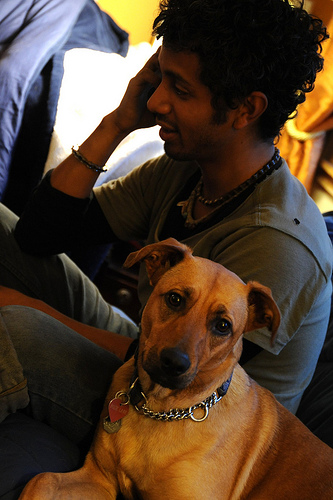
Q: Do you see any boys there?
A: No, there are no boys.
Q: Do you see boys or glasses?
A: No, there are no boys or glasses.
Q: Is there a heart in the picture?
A: Yes, there is a heart.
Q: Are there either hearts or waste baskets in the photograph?
A: Yes, there is a heart.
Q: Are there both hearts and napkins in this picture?
A: No, there is a heart but no napkins.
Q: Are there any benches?
A: No, there are no benches.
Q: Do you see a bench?
A: No, there are no benches.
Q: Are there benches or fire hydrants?
A: No, there are no benches or fire hydrants.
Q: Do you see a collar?
A: Yes, there is a collar.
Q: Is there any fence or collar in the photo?
A: Yes, there is a collar.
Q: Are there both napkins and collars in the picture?
A: No, there is a collar but no napkins.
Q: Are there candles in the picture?
A: No, there are no candles.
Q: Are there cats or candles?
A: No, there are no candles or cats.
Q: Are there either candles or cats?
A: No, there are no candles or cats.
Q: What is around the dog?
A: The collar is around the dog.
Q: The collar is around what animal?
A: The collar is around the dog.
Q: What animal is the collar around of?
A: The collar is around the dog.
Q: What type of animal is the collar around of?
A: The collar is around the dog.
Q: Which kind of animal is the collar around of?
A: The collar is around the dog.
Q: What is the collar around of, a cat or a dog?
A: The collar is around a dog.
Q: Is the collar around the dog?
A: Yes, the collar is around the dog.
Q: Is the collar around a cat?
A: No, the collar is around the dog.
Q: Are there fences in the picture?
A: No, there are no fences.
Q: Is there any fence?
A: No, there are no fences.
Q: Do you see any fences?
A: No, there are no fences.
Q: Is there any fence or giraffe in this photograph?
A: No, there are no fences or giraffes.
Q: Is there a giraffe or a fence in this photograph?
A: No, there are no fences or giraffes.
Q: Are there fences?
A: No, there are no fences.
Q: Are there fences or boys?
A: No, there are no fences or boys.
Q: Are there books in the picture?
A: No, there are no books.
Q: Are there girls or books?
A: No, there are no books or girls.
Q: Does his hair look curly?
A: Yes, the hair is curly.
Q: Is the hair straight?
A: No, the hair is curly.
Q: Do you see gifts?
A: No, there are no gifts.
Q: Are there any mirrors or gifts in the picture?
A: No, there are no gifts or mirrors.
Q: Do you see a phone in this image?
A: Yes, there is a phone.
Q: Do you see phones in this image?
A: Yes, there is a phone.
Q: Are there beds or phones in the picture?
A: Yes, there is a phone.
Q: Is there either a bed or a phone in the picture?
A: Yes, there is a phone.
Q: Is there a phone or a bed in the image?
A: Yes, there is a phone.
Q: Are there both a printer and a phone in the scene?
A: No, there is a phone but no printers.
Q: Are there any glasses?
A: No, there are no glasses.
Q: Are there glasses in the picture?
A: No, there are no glasses.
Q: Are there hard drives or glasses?
A: No, there are no glasses or hard drives.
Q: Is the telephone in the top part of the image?
A: Yes, the telephone is in the top of the image.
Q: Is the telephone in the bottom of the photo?
A: No, the telephone is in the top of the image.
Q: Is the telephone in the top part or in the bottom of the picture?
A: The telephone is in the top of the image.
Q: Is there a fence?
A: No, there are no fences.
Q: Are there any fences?
A: No, there are no fences.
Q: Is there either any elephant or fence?
A: No, there are no fences or elephants.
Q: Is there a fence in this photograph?
A: No, there are no fences.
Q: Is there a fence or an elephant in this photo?
A: No, there are no fences or elephants.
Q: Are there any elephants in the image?
A: No, there are no elephants.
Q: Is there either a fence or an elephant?
A: No, there are no elephants or fences.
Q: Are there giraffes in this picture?
A: No, there are no giraffes.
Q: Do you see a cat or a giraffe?
A: No, there are no giraffes or cats.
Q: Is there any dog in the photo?
A: Yes, there is a dog.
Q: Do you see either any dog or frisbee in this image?
A: Yes, there is a dog.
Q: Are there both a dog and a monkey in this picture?
A: No, there is a dog but no monkeys.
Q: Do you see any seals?
A: No, there are no seals.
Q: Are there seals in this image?
A: No, there are no seals.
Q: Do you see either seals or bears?
A: No, there are no seals or bears.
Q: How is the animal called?
A: The animal is a dog.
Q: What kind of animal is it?
A: The animal is a dog.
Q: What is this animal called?
A: That is a dog.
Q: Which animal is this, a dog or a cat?
A: That is a dog.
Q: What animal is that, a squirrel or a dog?
A: That is a dog.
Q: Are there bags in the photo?
A: No, there are no bags.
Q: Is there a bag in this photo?
A: No, there are no bags.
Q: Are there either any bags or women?
A: No, there are no bags or women.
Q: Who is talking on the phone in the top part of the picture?
A: The guy is talking on the phone.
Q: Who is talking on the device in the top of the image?
A: The guy is talking on the phone.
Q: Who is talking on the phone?
A: The guy is talking on the phone.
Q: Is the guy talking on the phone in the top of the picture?
A: Yes, the guy is talking on the phone.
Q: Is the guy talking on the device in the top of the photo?
A: Yes, the guy is talking on the phone.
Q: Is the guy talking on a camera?
A: No, the guy is talking on the phone.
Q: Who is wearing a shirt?
A: The guy is wearing a shirt.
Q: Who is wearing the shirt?
A: The guy is wearing a shirt.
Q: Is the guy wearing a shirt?
A: Yes, the guy is wearing a shirt.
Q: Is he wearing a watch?
A: No, the guy is wearing a shirt.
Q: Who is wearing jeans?
A: The guy is wearing jeans.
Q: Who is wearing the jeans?
A: The guy is wearing jeans.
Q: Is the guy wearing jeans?
A: Yes, the guy is wearing jeans.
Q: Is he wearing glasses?
A: No, the guy is wearing jeans.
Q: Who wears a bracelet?
A: The guy wears a bracelet.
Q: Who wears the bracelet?
A: The guy wears a bracelet.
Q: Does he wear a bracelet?
A: Yes, the guy wears a bracelet.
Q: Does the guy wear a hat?
A: No, the guy wears a bracelet.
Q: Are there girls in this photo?
A: No, there are no girls.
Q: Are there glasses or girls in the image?
A: No, there are no girls or glasses.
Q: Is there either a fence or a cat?
A: No, there are no fences or cats.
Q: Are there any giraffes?
A: No, there are no giraffes.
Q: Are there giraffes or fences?
A: No, there are no giraffes or fences.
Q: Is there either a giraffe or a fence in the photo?
A: No, there are no giraffes or fences.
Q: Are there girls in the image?
A: No, there are no girls.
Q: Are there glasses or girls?
A: No, there are no girls or glasses.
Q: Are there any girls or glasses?
A: No, there are no girls or glasses.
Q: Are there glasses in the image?
A: No, there are no glasses.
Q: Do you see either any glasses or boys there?
A: No, there are no glasses or boys.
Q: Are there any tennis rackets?
A: No, there are no tennis rackets.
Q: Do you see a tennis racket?
A: No, there are no rackets.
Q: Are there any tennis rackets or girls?
A: No, there are no tennis rackets or girls.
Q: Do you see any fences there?
A: No, there are no fences.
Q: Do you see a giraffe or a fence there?
A: No, there are no fences or giraffes.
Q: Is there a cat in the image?
A: No, there are no cats.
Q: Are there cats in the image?
A: No, there are no cats.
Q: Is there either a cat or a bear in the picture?
A: No, there are no cats or bears.